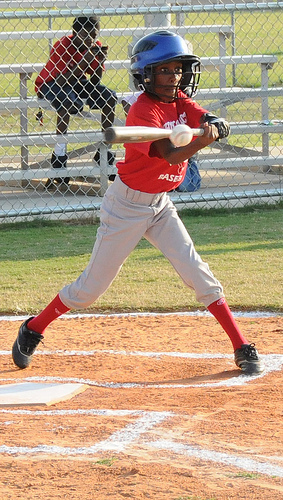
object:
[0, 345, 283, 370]
stripe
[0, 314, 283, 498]
dirt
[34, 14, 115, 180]
boy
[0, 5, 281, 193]
bleachers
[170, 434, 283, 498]
lines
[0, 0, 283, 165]
ground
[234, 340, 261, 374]
cleat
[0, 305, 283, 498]
clay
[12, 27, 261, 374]
he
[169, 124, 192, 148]
ball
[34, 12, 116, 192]
spectator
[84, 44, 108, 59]
phone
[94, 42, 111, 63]
game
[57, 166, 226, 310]
pants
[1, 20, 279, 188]
stands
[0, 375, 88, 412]
plate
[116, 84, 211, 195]
shirt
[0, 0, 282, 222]
fence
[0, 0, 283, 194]
wall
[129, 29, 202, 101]
helmet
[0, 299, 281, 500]
lines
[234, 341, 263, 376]
shoe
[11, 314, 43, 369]
shoe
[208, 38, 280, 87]
bleachers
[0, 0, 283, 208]
chain link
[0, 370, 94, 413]
home plate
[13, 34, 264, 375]
boy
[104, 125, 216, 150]
baseball bat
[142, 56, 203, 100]
face guard